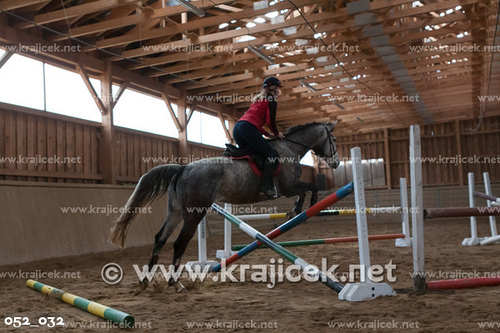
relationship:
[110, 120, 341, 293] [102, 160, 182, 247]
horse has tail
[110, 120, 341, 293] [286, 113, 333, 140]
horse has mane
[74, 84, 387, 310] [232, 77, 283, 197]
horse with girl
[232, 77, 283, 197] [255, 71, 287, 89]
girl wearing helmet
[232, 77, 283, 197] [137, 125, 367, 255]
girl on horse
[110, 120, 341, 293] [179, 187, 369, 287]
horse in structure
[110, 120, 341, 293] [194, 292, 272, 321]
horse on dirt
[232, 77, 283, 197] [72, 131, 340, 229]
girl on horse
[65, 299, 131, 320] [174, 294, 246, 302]
pole on ground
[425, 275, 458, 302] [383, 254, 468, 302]
pole on ground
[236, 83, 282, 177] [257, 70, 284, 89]
girl wears hat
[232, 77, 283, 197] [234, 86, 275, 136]
girl wears shirt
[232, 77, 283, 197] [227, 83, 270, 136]
girl in shirt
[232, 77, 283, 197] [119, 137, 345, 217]
girl riding horse